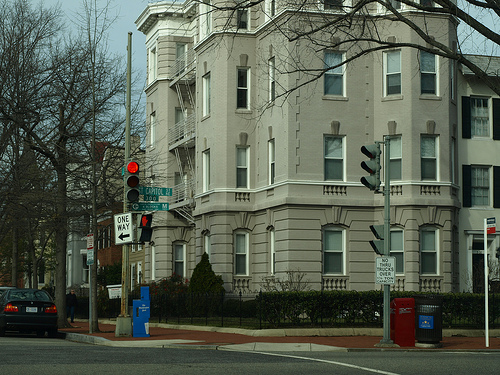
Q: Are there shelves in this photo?
A: No, there are no shelves.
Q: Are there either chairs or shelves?
A: No, there are no shelves or chairs.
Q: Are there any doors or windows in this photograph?
A: Yes, there are windows.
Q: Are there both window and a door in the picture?
A: No, there are windows but no doors.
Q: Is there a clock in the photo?
A: No, there are no clocks.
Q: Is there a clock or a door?
A: No, there are no clocks or doors.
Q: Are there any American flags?
A: No, there are no American flags.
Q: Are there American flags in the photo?
A: No, there are no American flags.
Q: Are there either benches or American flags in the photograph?
A: No, there are no American flags or benches.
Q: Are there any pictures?
A: No, there are no pictures.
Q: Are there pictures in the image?
A: No, there are no pictures.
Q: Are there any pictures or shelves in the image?
A: No, there are no pictures or shelves.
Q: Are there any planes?
A: No, there are no planes.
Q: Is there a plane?
A: No, there are no airplanes.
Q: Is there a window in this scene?
A: Yes, there are windows.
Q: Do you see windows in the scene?
A: Yes, there are windows.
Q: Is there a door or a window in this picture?
A: Yes, there are windows.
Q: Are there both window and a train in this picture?
A: No, there are windows but no trains.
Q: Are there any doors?
A: No, there are no doors.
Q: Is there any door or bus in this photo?
A: No, there are no doors or buses.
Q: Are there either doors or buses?
A: No, there are no doors or buses.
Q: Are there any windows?
A: Yes, there is a window.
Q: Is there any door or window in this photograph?
A: Yes, there is a window.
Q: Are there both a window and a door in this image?
A: No, there is a window but no doors.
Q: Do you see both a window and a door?
A: No, there is a window but no doors.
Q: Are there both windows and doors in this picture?
A: No, there is a window but no doors.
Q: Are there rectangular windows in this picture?
A: Yes, there is a rectangular window.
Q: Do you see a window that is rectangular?
A: Yes, there is a rectangular window.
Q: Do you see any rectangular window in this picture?
A: Yes, there is a rectangular window.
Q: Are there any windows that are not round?
A: Yes, there is a rectangular window.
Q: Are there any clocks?
A: No, there are no clocks.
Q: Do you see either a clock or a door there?
A: No, there are no clocks or doors.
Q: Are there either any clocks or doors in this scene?
A: No, there are no clocks or doors.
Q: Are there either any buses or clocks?
A: No, there are no buses or clocks.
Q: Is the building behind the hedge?
A: Yes, the building is behind the hedge.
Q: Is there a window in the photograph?
A: Yes, there is a window.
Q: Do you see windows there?
A: Yes, there is a window.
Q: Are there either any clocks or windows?
A: Yes, there is a window.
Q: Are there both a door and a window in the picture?
A: No, there is a window but no doors.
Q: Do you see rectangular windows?
A: Yes, there is a rectangular window.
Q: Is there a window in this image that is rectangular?
A: Yes, there is a window that is rectangular.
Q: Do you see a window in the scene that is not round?
A: Yes, there is a rectangular window.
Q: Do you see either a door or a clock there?
A: No, there are no doors or clocks.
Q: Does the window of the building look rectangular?
A: Yes, the window is rectangular.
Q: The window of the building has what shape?
A: The window is rectangular.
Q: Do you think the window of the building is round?
A: No, the window is rectangular.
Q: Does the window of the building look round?
A: No, the window is rectangular.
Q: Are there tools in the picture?
A: No, there are no tools.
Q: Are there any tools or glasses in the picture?
A: No, there are no tools or glasses.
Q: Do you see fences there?
A: Yes, there is a fence.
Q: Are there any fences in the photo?
A: Yes, there is a fence.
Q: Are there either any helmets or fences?
A: Yes, there is a fence.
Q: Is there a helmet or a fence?
A: Yes, there is a fence.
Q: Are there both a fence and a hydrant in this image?
A: No, there is a fence but no fire hydrants.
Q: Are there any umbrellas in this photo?
A: No, there are no umbrellas.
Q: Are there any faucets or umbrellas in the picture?
A: No, there are no umbrellas or faucets.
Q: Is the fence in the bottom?
A: Yes, the fence is in the bottom of the image.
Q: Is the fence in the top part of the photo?
A: No, the fence is in the bottom of the image.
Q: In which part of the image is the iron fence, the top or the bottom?
A: The fence is in the bottom of the image.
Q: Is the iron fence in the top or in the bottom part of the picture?
A: The fence is in the bottom of the image.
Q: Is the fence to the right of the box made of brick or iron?
A: The fence is made of iron.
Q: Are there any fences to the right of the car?
A: Yes, there is a fence to the right of the car.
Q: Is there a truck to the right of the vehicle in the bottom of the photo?
A: No, there is a fence to the right of the car.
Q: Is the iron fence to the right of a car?
A: Yes, the fence is to the right of a car.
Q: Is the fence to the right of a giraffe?
A: No, the fence is to the right of a car.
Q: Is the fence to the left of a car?
A: No, the fence is to the right of a car.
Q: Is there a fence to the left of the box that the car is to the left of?
A: No, the fence is to the right of the box.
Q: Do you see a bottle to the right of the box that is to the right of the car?
A: No, there is a fence to the right of the box.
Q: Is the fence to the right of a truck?
A: No, the fence is to the right of the box.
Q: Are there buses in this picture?
A: No, there are no buses.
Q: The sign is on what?
A: The sign is on the pole.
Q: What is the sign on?
A: The sign is on the pole.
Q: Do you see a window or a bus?
A: Yes, there are windows.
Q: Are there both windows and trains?
A: No, there are windows but no trains.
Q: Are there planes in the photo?
A: No, there are no planes.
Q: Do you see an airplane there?
A: No, there are no airplanes.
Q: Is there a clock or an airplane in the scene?
A: No, there are no airplanes or clocks.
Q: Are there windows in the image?
A: Yes, there is a window.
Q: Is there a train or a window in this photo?
A: Yes, there is a window.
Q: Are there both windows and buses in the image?
A: No, there is a window but no buses.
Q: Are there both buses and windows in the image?
A: No, there is a window but no buses.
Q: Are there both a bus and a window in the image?
A: No, there is a window but no buses.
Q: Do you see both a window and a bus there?
A: No, there is a window but no buses.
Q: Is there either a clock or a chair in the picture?
A: No, there are no chairs or clocks.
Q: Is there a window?
A: Yes, there is a window.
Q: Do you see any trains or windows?
A: Yes, there is a window.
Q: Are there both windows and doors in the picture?
A: No, there is a window but no doors.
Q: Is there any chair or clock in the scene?
A: No, there are no chairs or clocks.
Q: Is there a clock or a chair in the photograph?
A: No, there are no chairs or clocks.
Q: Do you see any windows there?
A: Yes, there is a window.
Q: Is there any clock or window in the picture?
A: Yes, there is a window.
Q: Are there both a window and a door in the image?
A: No, there is a window but no doors.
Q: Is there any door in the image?
A: No, there are no doors.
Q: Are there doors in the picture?
A: No, there are no doors.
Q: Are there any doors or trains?
A: No, there are no doors or trains.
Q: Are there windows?
A: Yes, there is a window.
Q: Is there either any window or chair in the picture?
A: Yes, there is a window.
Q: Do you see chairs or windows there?
A: Yes, there is a window.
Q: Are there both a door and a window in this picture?
A: No, there is a window but no doors.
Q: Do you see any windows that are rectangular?
A: Yes, there is a rectangular window.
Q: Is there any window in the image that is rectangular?
A: Yes, there is a window that is rectangular.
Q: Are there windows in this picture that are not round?
A: Yes, there is a rectangular window.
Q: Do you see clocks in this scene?
A: No, there are no clocks.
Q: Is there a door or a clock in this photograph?
A: No, there are no clocks or doors.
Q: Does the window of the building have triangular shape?
A: No, the window is rectangular.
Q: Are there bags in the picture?
A: No, there are no bags.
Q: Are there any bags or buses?
A: No, there are no bags or buses.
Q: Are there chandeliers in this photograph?
A: No, there are no chandeliers.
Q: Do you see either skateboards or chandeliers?
A: No, there are no chandeliers or skateboards.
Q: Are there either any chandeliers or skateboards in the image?
A: No, there are no chandeliers or skateboards.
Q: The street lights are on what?
A: The street lights are on the pole.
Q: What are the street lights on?
A: The street lights are on the pole.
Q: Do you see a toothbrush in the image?
A: No, there are no toothbrushes.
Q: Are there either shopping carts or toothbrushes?
A: No, there are no toothbrushes or shopping carts.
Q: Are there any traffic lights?
A: Yes, there is a traffic light.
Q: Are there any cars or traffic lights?
A: Yes, there is a traffic light.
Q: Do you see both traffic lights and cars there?
A: Yes, there are both a traffic light and a car.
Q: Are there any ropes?
A: No, there are no ropes.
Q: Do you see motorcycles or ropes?
A: No, there are no ropes or motorcycles.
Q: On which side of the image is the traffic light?
A: The traffic light is on the left of the image.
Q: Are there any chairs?
A: No, there are no chairs.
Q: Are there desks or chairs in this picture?
A: No, there are no chairs or desks.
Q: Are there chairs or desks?
A: No, there are no chairs or desks.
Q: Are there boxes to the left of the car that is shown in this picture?
A: No, the box is to the right of the car.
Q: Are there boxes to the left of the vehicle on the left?
A: No, the box is to the right of the car.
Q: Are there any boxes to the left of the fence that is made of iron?
A: Yes, there is a box to the left of the fence.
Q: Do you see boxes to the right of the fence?
A: No, the box is to the left of the fence.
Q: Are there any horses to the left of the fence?
A: No, there is a box to the left of the fence.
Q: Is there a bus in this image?
A: No, there are no buses.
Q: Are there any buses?
A: No, there are no buses.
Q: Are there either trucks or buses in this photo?
A: No, there are no buses or trucks.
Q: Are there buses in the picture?
A: No, there are no buses.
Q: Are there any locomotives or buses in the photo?
A: No, there are no buses or locomotives.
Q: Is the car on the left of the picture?
A: Yes, the car is on the left of the image.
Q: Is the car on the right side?
A: No, the car is on the left of the image.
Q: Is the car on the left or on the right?
A: The car is on the left of the image.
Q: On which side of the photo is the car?
A: The car is on the left of the image.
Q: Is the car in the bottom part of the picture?
A: Yes, the car is in the bottom of the image.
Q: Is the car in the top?
A: No, the car is in the bottom of the image.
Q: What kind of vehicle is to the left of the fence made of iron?
A: The vehicle is a car.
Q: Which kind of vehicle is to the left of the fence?
A: The vehicle is a car.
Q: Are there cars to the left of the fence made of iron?
A: Yes, there is a car to the left of the fence.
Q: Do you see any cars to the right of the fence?
A: No, the car is to the left of the fence.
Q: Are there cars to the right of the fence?
A: No, the car is to the left of the fence.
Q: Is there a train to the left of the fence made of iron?
A: No, there is a car to the left of the fence.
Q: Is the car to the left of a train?
A: No, the car is to the left of a fence.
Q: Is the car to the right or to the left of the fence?
A: The car is to the left of the fence.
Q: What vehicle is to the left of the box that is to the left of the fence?
A: The vehicle is a car.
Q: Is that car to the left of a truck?
A: No, the car is to the left of the box.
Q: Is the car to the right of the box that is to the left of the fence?
A: No, the car is to the left of the box.